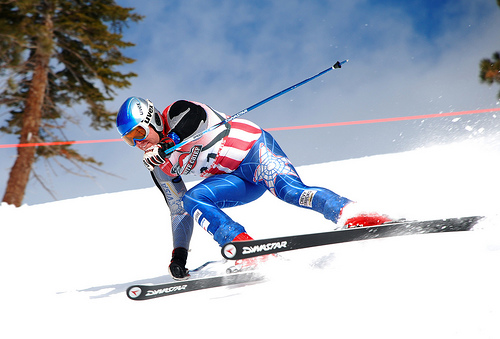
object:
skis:
[128, 203, 468, 295]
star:
[252, 140, 302, 199]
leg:
[237, 132, 390, 224]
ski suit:
[142, 95, 409, 264]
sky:
[242, 13, 355, 34]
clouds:
[248, 12, 296, 61]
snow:
[3, 148, 491, 317]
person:
[114, 95, 411, 284]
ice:
[0, 132, 500, 335]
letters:
[145, 283, 194, 296]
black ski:
[222, 217, 479, 263]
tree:
[25, 26, 120, 118]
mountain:
[35, 181, 455, 330]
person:
[113, 94, 395, 270]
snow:
[1, 137, 499, 337]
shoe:
[336, 202, 403, 242]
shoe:
[226, 232, 283, 279]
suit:
[113, 91, 401, 275]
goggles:
[122, 98, 160, 145]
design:
[221, 243, 239, 263]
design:
[121, 280, 148, 302]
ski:
[113, 251, 471, 307]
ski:
[214, 211, 489, 265]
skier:
[114, 95, 399, 280]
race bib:
[191, 146, 223, 177]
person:
[100, 92, 385, 302]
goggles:
[119, 126, 162, 152]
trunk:
[0, 0, 117, 203]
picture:
[7, 5, 495, 331]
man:
[114, 93, 405, 282]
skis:
[124, 212, 499, 302]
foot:
[336, 204, 397, 236]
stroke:
[164, 57, 353, 155]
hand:
[138, 134, 176, 173]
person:
[72, 86, 379, 286]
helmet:
[86, 89, 195, 153]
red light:
[1, 102, 498, 154]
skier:
[113, 57, 482, 300]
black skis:
[123, 209, 479, 309]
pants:
[178, 150, 390, 242]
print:
[238, 239, 295, 258]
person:
[110, 92, 485, 301]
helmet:
[89, 86, 212, 151]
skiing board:
[218, 209, 483, 266]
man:
[66, 60, 407, 263]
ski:
[218, 210, 488, 259]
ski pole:
[157, 52, 348, 166]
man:
[111, 88, 391, 258]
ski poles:
[176, 59, 350, 278]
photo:
[6, 4, 490, 332]